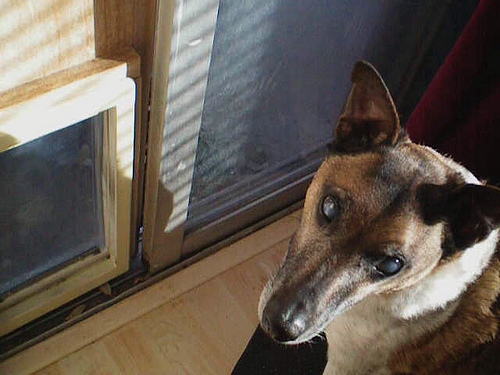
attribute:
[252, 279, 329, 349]
dog — brown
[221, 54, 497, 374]
dog — brown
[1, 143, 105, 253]
flowers — orange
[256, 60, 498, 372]
dog — brown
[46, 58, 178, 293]
board — wooden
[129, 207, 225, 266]
sheep —  white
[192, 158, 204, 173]
grass — green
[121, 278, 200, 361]
sheep — white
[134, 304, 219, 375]
grass — green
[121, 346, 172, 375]
grass — green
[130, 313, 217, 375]
sheep — white